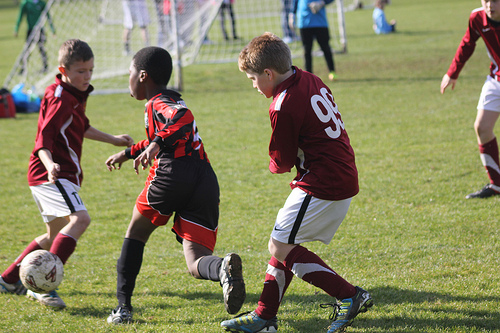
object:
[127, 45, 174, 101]
head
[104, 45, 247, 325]
boy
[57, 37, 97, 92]
head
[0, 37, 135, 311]
boy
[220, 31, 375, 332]
boy